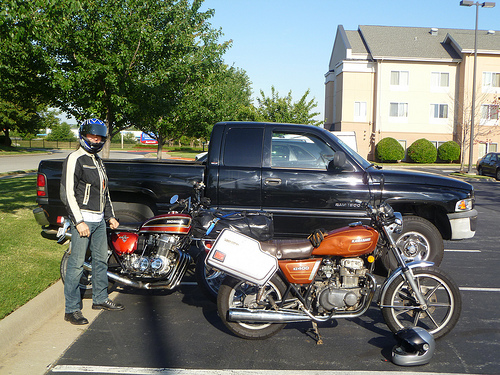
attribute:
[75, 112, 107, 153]
helmet — black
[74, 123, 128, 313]
man — standing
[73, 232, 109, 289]
jeans — blue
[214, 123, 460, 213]
truck — parked, black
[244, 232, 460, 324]
bike — standing, orange, red, parked, gray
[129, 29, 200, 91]
tree — green